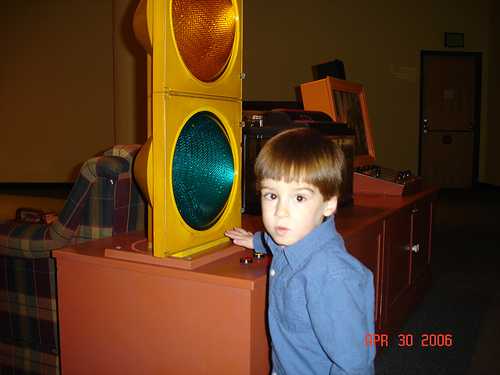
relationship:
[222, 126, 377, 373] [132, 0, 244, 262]
boy near stoplight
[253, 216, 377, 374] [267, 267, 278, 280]
shirt has button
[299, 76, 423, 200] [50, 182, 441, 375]
computer on top of table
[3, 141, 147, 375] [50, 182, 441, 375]
chair behind table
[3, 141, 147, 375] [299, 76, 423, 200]
chair behind computer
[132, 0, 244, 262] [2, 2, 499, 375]
stoplight in room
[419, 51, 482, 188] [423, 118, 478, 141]
door has bar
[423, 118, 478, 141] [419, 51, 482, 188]
bar on door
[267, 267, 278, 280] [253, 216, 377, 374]
button on shirt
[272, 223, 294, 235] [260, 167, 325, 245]
lips on face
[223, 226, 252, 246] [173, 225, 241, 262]
fingers on surface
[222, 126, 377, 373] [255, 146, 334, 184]
boy has bangs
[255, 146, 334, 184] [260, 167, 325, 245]
bangs on face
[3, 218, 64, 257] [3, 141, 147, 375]
arm of sofa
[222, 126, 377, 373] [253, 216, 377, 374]
boy wearing shirt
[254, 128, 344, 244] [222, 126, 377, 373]
head of boy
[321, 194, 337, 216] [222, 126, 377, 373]
ear of boy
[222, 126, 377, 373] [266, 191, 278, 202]
boy's left eye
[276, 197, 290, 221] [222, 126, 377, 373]
nose of boy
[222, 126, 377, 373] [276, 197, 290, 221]
boy has a nose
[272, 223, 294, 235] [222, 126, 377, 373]
mouth of boy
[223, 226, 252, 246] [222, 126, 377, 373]
hand of boy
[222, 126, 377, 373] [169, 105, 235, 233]
boy by light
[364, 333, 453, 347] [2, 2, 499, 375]
date on photo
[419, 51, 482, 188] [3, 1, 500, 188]
door in background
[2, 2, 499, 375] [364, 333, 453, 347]
photo has date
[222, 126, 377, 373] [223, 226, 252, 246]
boy has a hand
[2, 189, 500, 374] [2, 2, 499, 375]
floor of room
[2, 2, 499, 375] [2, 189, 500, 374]
room has a floor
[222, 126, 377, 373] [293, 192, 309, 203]
boy has eye